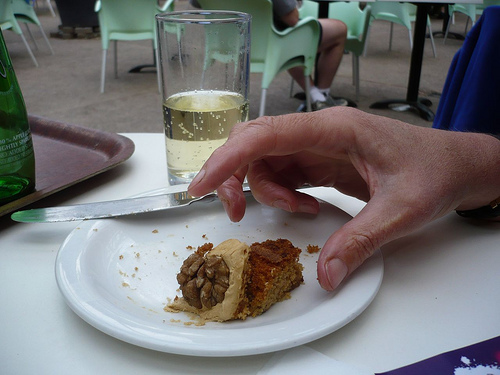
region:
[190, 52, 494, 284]
hand of a person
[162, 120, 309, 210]
finger of a person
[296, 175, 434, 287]
thumb of a person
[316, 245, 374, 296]
nail of a person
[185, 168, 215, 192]
nail of a person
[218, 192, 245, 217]
nail of a person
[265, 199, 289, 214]
nail of a person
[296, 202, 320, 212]
nail of a person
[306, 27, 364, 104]
leg of a person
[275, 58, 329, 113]
leg of a person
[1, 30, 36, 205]
a green empty bottle on a tray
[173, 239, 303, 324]
a half finished pastry on a plate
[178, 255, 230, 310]
crushed walnuts on a brown frosting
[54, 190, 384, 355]
a small white plate on a table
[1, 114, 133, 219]
a brown tray on a table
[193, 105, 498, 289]
a and about to pick a pastry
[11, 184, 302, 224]
a knife propped on a plate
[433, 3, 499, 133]
edge of a blue shirt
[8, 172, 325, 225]
Knife on a plate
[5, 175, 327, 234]
Knife is on a plate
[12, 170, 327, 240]
Knife on a white plate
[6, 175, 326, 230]
Knife is on a white plate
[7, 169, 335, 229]
Knife on a round plate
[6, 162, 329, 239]
Knife is on a round plate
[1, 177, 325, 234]
Knife on a round white plate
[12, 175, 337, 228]
Knife is on a round white plate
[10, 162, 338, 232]
Butter knife on a round white plate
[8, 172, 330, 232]
Butter knife is on a round white plate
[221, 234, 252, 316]
gravy on the food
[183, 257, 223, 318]
nuts on the end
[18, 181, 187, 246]
knife on the plate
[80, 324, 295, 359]
plate is white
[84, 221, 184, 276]
crumbs on the plate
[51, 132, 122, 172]
tray is brown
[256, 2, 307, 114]
chair is light green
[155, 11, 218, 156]
glass filled with liquid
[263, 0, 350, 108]
person sitting in green chair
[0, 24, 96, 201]
green bottle on the tray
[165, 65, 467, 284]
hand of a person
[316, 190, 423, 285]
thumb of a person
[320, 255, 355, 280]
nail of a person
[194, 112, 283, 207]
finger of a person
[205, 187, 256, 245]
finger of a person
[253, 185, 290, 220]
finger of a person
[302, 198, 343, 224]
finger of a person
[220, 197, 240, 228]
nail of a person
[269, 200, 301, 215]
nail of a person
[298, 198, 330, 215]
nail of a person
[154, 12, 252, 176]
clear glass with a beverage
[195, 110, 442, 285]
a person's hand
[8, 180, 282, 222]
the butter knife is metal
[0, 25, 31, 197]
bottle made of green glass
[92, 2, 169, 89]
the chair is green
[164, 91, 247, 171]
the liquid is pale yellow